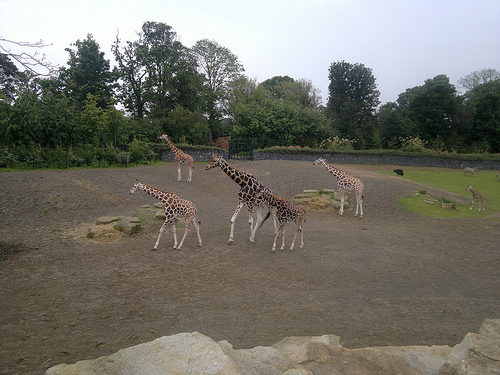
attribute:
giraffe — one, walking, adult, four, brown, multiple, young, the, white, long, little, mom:
[126, 167, 211, 277]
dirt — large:
[148, 244, 209, 271]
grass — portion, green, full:
[127, 129, 162, 156]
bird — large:
[384, 158, 413, 189]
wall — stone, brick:
[169, 332, 195, 359]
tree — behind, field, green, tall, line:
[54, 72, 137, 167]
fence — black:
[291, 143, 335, 155]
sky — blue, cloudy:
[287, 12, 325, 52]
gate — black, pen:
[228, 145, 260, 166]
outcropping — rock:
[38, 185, 86, 217]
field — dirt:
[86, 259, 251, 375]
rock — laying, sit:
[175, 333, 215, 368]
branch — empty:
[79, 69, 146, 145]